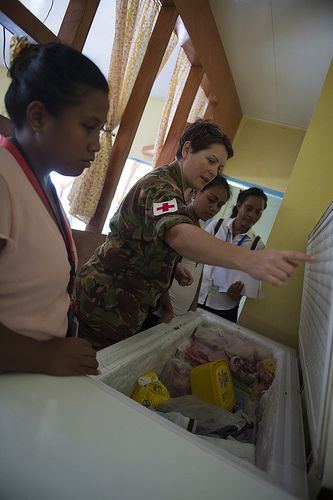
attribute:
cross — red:
[154, 202, 175, 211]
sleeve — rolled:
[141, 164, 191, 248]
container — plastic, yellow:
[190, 359, 238, 413]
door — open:
[296, 200, 331, 488]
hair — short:
[173, 120, 235, 161]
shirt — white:
[198, 218, 268, 312]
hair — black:
[4, 36, 108, 134]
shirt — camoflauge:
[72, 159, 196, 343]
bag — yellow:
[129, 370, 172, 408]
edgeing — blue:
[220, 174, 286, 199]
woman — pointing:
[73, 117, 316, 349]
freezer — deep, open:
[84, 204, 332, 498]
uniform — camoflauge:
[73, 157, 197, 354]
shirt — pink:
[0, 136, 79, 339]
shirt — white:
[154, 256, 204, 318]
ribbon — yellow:
[11, 34, 28, 64]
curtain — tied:
[66, 3, 165, 226]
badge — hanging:
[68, 313, 80, 341]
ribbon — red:
[2, 136, 78, 309]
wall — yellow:
[220, 61, 333, 351]